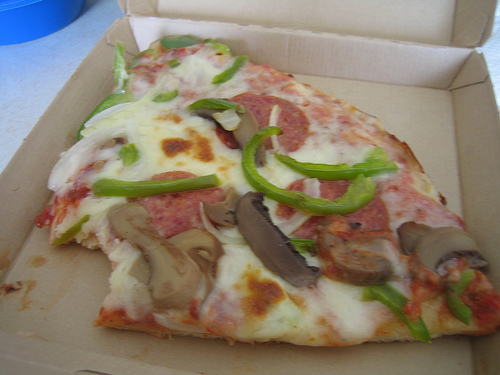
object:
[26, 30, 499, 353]
pizza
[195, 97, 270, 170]
mushroom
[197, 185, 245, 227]
mushroom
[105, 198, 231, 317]
mushroom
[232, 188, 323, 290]
mushroom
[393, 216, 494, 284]
mushroom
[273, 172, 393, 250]
pepperoni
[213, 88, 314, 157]
pepperoni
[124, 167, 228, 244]
pepperoni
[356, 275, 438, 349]
peppers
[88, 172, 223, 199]
peppers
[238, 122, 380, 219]
peppers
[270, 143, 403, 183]
peppers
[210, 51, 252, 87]
peppers